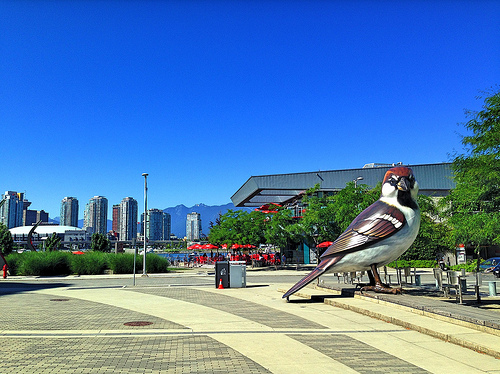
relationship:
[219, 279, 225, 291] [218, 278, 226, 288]
white orange cone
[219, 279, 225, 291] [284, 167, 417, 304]
white brown bird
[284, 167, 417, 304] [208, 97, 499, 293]
large green trees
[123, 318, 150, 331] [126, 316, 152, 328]
manhole on ground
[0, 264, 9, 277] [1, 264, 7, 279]
red fire hydrant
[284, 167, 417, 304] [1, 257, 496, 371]
statue on walkway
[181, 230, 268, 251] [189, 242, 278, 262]
umbrellas are on table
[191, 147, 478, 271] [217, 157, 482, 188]
building on roof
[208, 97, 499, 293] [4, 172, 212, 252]
trees next to building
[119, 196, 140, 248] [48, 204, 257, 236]
building in front of mountain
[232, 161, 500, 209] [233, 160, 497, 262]
overhanging of building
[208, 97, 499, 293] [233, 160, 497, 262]
trees surround building